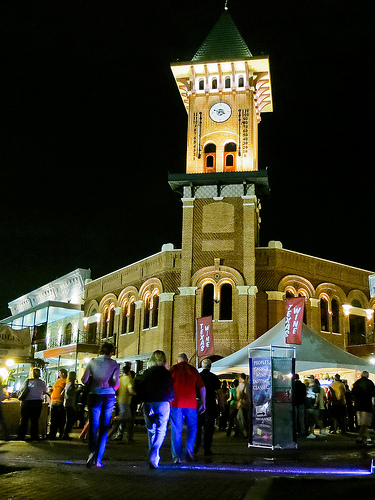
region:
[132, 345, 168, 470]
a person standing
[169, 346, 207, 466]
a person standing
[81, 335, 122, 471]
a person standing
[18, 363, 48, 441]
a person standing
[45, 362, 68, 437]
a person standing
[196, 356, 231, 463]
a person standing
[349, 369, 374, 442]
a person standing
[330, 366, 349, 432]
a person standing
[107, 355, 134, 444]
a person standing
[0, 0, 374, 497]
it is a nighttime scene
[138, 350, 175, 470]
Woman going to wine festival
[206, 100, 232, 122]
clock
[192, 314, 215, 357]
Red and white sign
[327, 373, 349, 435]
Man at a festival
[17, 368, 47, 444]
woman with purse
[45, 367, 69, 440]
man watching vendor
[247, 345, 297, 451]
advertisement and map area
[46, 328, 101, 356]
Balcony of brick building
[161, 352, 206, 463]
man in red shirt looking down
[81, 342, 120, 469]
woman with purse walking slowly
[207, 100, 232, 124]
a clock on clock tower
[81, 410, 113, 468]
a womans legs and feet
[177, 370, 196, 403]
a bald mans red shirt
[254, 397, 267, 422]
a sign with an arrow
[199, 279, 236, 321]
old windows on a building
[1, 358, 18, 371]
lights on a booth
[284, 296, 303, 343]
a red sign with white text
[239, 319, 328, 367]
a white tent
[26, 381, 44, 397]
woman with pink shirt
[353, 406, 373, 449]
shorts on a man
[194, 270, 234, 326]
window on a building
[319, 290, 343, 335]
window on a building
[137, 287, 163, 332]
window on a building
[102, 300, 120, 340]
window on a building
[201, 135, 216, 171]
window on a building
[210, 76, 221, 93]
window on a building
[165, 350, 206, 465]
the man in the red tshirt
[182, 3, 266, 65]
the roof of the clock tower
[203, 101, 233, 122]
the clock on the clock tower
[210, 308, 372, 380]
the white canopy tent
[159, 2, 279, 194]
the illuminated clock tower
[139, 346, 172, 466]
the woman behind the man in the red shirt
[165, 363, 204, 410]
the man's red tshirt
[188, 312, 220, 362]
the sign above the man's head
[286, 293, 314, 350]
the sign on the canopy tent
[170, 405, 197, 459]
the jeans of the man in the red tshirt